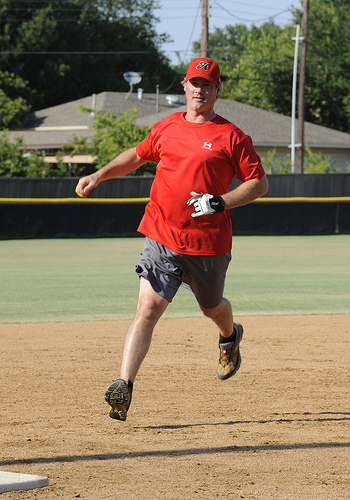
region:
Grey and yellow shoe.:
[207, 320, 253, 383]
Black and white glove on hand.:
[185, 186, 229, 221]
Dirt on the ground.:
[3, 320, 349, 498]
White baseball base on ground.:
[0, 464, 52, 498]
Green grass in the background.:
[0, 238, 349, 318]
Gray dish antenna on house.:
[118, 67, 151, 108]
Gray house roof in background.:
[10, 83, 348, 164]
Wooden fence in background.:
[1, 175, 349, 236]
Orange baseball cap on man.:
[175, 53, 228, 119]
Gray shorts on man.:
[126, 51, 247, 311]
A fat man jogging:
[67, 64, 256, 418]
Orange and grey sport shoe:
[96, 367, 144, 424]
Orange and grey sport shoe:
[212, 332, 237, 380]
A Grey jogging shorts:
[147, 238, 232, 309]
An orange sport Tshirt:
[128, 97, 245, 247]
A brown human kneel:
[137, 301, 162, 320]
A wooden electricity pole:
[200, 4, 215, 57]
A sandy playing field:
[168, 390, 292, 490]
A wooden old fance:
[6, 177, 70, 195]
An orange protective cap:
[186, 58, 225, 84]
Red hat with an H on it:
[163, 45, 246, 120]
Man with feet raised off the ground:
[79, 309, 278, 424]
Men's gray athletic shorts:
[120, 228, 256, 309]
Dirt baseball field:
[9, 346, 324, 495]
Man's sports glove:
[178, 187, 249, 247]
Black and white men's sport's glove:
[174, 185, 238, 227]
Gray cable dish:
[113, 48, 160, 110]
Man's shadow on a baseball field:
[143, 316, 340, 440]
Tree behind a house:
[221, 26, 349, 200]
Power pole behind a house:
[184, 2, 281, 126]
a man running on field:
[73, 55, 270, 423]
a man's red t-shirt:
[136, 109, 265, 256]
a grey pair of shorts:
[135, 231, 230, 311]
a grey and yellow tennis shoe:
[214, 322, 243, 382]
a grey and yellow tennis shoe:
[103, 376, 132, 423]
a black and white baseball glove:
[184, 188, 224, 218]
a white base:
[0, 468, 53, 495]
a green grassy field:
[4, 234, 349, 324]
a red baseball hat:
[182, 56, 221, 83]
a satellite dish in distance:
[118, 67, 144, 99]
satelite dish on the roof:
[121, 65, 153, 101]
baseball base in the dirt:
[15, 446, 53, 493]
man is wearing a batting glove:
[192, 186, 218, 223]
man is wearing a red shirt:
[156, 131, 187, 205]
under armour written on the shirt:
[195, 129, 223, 148]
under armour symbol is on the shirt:
[201, 134, 219, 149]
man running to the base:
[124, 337, 254, 427]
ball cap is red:
[176, 53, 215, 81]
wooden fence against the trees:
[283, 162, 333, 246]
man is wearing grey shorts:
[165, 250, 230, 306]